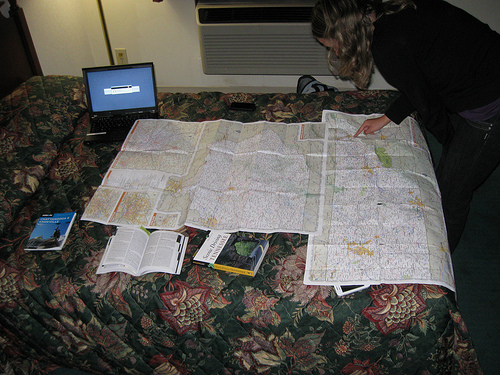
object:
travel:
[27, 219, 66, 248]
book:
[21, 202, 80, 255]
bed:
[0, 63, 484, 375]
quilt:
[159, 280, 284, 335]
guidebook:
[188, 225, 275, 281]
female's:
[304, 0, 500, 257]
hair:
[301, 1, 393, 97]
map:
[72, 111, 332, 238]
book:
[94, 221, 194, 282]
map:
[295, 103, 462, 300]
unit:
[189, 14, 342, 77]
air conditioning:
[256, 4, 300, 22]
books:
[189, 223, 272, 279]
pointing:
[352, 131, 367, 138]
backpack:
[286, 71, 344, 99]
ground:
[459, 244, 499, 313]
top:
[373, 0, 493, 45]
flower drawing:
[13, 120, 70, 168]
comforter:
[1, 102, 81, 173]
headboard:
[0, 0, 45, 86]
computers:
[75, 59, 166, 149]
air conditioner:
[193, 0, 335, 80]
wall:
[12, 0, 206, 92]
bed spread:
[58, 133, 111, 173]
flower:
[31, 147, 50, 162]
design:
[100, 82, 146, 97]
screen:
[83, 65, 159, 110]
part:
[108, 57, 116, 65]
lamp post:
[87, 0, 115, 64]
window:
[177, 0, 234, 9]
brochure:
[326, 282, 374, 299]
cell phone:
[223, 98, 260, 116]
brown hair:
[324, 25, 378, 93]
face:
[323, 38, 349, 61]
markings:
[361, 247, 367, 250]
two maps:
[79, 103, 459, 294]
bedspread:
[3, 270, 69, 300]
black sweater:
[369, 0, 499, 124]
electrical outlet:
[108, 46, 134, 67]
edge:
[11, 0, 42, 74]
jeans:
[435, 117, 500, 255]